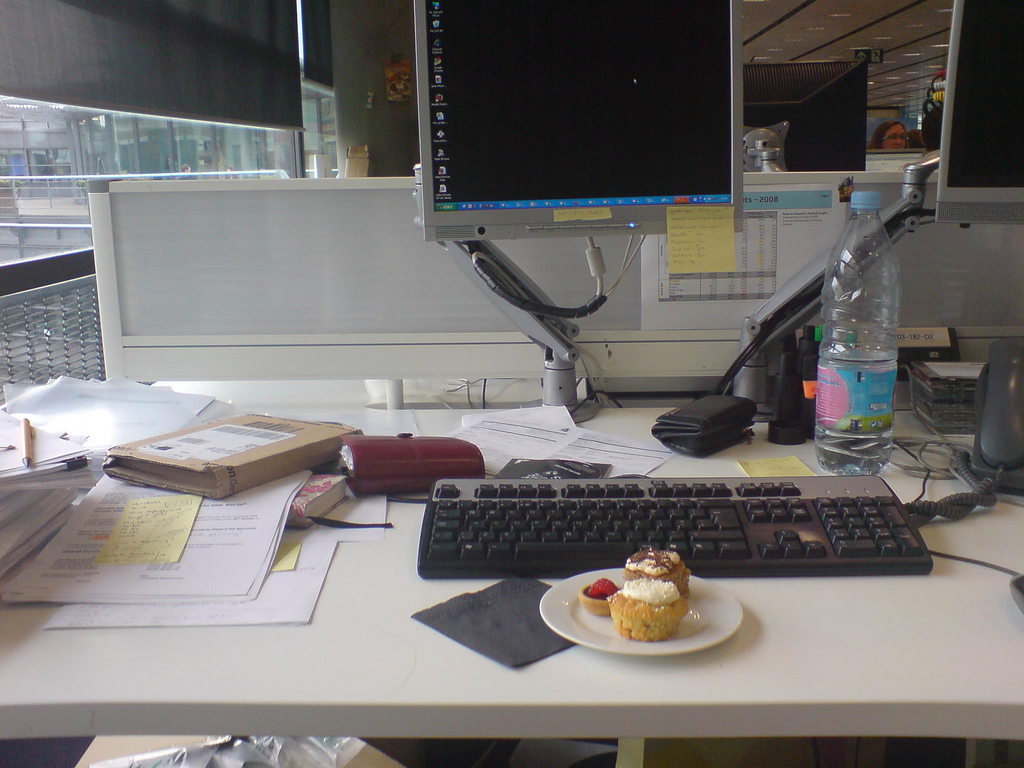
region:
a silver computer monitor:
[405, 4, 775, 235]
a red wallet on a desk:
[332, 425, 503, 499]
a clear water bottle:
[822, 184, 900, 492]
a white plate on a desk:
[544, 529, 735, 665]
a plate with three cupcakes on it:
[528, 544, 753, 662]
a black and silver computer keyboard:
[417, 477, 952, 576]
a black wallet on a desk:
[656, 380, 768, 464]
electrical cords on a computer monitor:
[500, 234, 649, 326]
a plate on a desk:
[492, 555, 756, 677]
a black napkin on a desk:
[408, 580, 535, 678]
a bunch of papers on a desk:
[48, 460, 355, 650]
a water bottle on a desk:
[792, 170, 916, 481]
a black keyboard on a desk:
[390, 459, 925, 564]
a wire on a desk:
[934, 536, 1021, 638]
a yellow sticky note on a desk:
[731, 445, 818, 493]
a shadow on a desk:
[8, 625, 56, 655]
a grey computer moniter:
[365, 15, 780, 235]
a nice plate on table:
[528, 535, 819, 731]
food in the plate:
[559, 540, 766, 697]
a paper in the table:
[405, 568, 622, 733]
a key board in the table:
[379, 435, 882, 592]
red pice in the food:
[575, 566, 634, 609]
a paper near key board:
[53, 477, 306, 615]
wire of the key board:
[922, 515, 1017, 601]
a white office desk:
[0, 380, 1021, 741]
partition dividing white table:
[1, 170, 1019, 741]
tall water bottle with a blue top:
[816, 188, 900, 474]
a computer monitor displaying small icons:
[409, 2, 746, 243]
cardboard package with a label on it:
[105, 413, 362, 502]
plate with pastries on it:
[539, 546, 743, 658]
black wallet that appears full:
[650, 393, 755, 461]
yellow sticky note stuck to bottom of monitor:
[413, 1, 743, 277]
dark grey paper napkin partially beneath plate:
[409, 549, 742, 668]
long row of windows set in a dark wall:
[0, 2, 307, 338]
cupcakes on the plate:
[561, 541, 701, 647]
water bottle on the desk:
[811, 173, 910, 471]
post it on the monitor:
[659, 200, 746, 281]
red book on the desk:
[331, 407, 483, 505]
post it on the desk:
[733, 445, 819, 487]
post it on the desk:
[108, 480, 208, 576]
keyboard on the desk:
[417, 473, 939, 576]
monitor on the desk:
[398, 4, 752, 246]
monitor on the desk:
[934, 2, 1017, 241]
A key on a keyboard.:
[764, 535, 787, 559]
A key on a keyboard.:
[784, 542, 803, 553]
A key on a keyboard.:
[805, 541, 821, 557]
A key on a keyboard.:
[778, 526, 795, 540]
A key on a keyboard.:
[897, 523, 916, 550]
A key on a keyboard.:
[879, 535, 900, 548]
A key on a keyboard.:
[720, 535, 752, 554]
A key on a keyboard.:
[689, 536, 715, 555]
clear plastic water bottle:
[827, 189, 888, 462]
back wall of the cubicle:
[100, 186, 421, 354]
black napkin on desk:
[424, 574, 541, 655]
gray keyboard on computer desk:
[418, 465, 899, 555]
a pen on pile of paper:
[16, 411, 45, 482]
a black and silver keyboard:
[413, 472, 932, 581]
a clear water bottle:
[813, 187, 902, 475]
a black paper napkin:
[412, 571, 574, 667]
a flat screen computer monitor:
[408, 0, 748, 242]